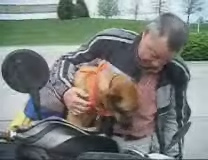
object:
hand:
[61, 86, 94, 115]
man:
[43, 13, 191, 160]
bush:
[180, 35, 208, 61]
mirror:
[0, 48, 50, 93]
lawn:
[0, 18, 208, 46]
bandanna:
[87, 63, 114, 117]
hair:
[143, 13, 188, 52]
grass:
[0, 16, 208, 46]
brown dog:
[65, 57, 141, 131]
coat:
[47, 27, 192, 160]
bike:
[0, 48, 108, 160]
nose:
[119, 113, 134, 129]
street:
[0, 45, 208, 160]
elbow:
[49, 45, 92, 76]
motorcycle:
[0, 48, 191, 160]